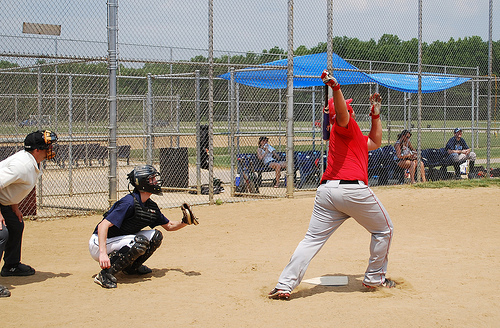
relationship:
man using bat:
[269, 67, 408, 306] [318, 81, 335, 144]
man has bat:
[269, 67, 408, 306] [318, 81, 335, 144]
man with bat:
[269, 67, 408, 306] [318, 81, 335, 144]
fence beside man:
[3, 0, 498, 179] [269, 67, 408, 306]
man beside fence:
[269, 67, 408, 306] [3, 0, 498, 179]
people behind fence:
[242, 118, 479, 194] [3, 0, 498, 179]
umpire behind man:
[1, 124, 66, 305] [269, 67, 408, 306]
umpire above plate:
[1, 124, 66, 305] [297, 268, 354, 294]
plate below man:
[297, 268, 354, 294] [269, 67, 408, 306]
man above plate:
[269, 67, 408, 306] [297, 268, 354, 294]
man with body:
[269, 67, 408, 306] [268, 65, 396, 297]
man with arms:
[269, 67, 408, 306] [317, 67, 383, 147]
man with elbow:
[269, 67, 408, 306] [162, 219, 178, 234]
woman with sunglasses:
[393, 128, 426, 181] [402, 132, 412, 138]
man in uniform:
[442, 128, 478, 178] [447, 137, 478, 177]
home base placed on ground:
[306, 272, 352, 286] [1, 184, 499, 324]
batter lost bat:
[269, 67, 396, 301] [246, 158, 264, 193]